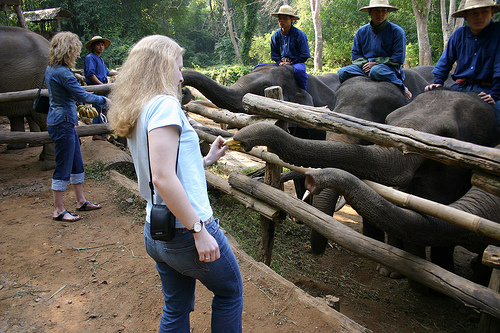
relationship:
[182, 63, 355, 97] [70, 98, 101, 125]
elephant eats bananas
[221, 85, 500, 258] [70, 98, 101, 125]
elephant eats bananas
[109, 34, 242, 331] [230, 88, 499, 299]
lady feeds elephant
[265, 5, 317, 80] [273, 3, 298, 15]
man wears hat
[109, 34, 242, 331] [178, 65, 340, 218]
lady feeds elephant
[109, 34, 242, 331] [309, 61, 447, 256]
lady feeds elephant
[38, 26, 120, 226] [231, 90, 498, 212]
woman feeds elephant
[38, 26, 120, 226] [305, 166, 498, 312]
woman feeds elephant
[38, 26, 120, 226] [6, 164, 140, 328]
woman on dirt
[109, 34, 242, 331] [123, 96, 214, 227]
lady wears t-shirt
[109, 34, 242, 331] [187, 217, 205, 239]
lady wears watch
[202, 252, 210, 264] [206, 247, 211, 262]
ring on finger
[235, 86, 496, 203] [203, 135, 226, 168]
elephant eats from hand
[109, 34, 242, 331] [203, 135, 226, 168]
lady has hand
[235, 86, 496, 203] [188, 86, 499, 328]
elephant behind fence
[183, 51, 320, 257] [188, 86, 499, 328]
elephant behind fence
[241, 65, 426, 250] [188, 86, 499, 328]
elephant behind fence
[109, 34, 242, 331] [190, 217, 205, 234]
lady wears watch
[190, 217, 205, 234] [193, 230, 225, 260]
watch in right hand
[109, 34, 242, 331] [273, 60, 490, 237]
lady on elephant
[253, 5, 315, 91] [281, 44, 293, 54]
man wears shirt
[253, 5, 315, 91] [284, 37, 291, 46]
man wears hat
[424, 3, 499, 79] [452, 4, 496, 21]
person wears hat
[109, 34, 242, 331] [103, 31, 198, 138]
lady has blonde hair